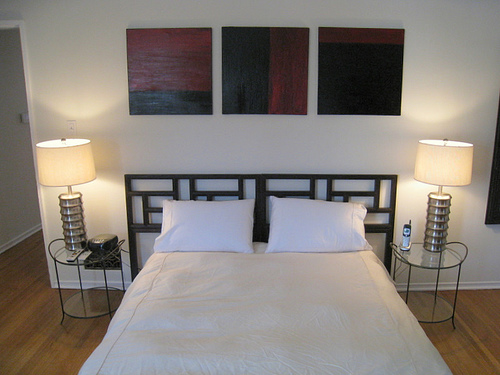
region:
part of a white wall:
[426, 20, 487, 93]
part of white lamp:
[412, 142, 469, 185]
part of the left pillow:
[283, 204, 353, 251]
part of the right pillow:
[165, 210, 242, 254]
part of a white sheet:
[210, 281, 359, 350]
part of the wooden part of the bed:
[346, 162, 389, 210]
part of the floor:
[13, 318, 55, 364]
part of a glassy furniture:
[416, 250, 447, 275]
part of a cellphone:
[396, 219, 413, 248]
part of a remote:
[66, 244, 78, 262]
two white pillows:
[149, 181, 376, 257]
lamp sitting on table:
[30, 133, 121, 269]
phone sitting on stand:
[396, 221, 417, 253]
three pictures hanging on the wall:
[117, 16, 418, 121]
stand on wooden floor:
[386, 238, 476, 334]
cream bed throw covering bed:
[146, 244, 396, 365]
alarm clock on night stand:
[87, 227, 120, 264]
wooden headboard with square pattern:
[120, 165, 398, 201]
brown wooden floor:
[13, 301, 55, 360]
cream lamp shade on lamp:
[410, 132, 478, 207]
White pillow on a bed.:
[154, 194, 256, 257]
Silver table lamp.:
[425, 186, 451, 259]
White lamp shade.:
[33, 133, 99, 190]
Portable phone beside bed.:
[404, 215, 416, 250]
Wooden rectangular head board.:
[113, 163, 405, 286]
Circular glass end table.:
[45, 232, 123, 328]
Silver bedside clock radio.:
[86, 230, 121, 255]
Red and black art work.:
[117, 21, 217, 116]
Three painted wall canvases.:
[110, 16, 415, 131]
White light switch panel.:
[16, 106, 31, 128]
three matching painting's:
[114, 14, 422, 124]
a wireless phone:
[395, 215, 414, 258]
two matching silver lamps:
[30, 128, 480, 261]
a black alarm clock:
[86, 230, 121, 260]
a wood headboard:
[114, 167, 406, 289]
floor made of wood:
[5, 249, 98, 366]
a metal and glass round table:
[387, 234, 470, 328]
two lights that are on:
[21, 128, 480, 267]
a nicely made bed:
[87, 193, 465, 373]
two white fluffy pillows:
[150, 191, 382, 251]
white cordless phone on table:
[396, 216, 424, 257]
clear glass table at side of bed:
[393, 234, 482, 328]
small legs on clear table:
[419, 266, 473, 326]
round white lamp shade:
[413, 129, 482, 197]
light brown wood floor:
[20, 307, 89, 352]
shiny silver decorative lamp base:
[425, 190, 459, 265]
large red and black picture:
[120, 17, 224, 134]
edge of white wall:
[15, 91, 53, 118]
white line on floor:
[473, 324, 488, 357]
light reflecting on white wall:
[413, 64, 464, 127]